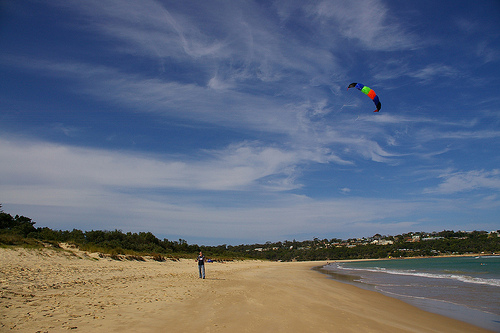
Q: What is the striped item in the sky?
A: A kite.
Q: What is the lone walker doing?
A: Flying a kite.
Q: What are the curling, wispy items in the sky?
A: Clouds.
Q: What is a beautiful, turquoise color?
A: The water, near the sand.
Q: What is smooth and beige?
A: The beach sand.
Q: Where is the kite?
A: Sky.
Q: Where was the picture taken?
A: Beach.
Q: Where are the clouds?
A: Sky.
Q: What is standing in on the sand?
A: A person.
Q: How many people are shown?
A: One person.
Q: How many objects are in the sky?
A: One.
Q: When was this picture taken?
A: In the daytime.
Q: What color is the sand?
A: Beige and light brown.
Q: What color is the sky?
A: Blue.